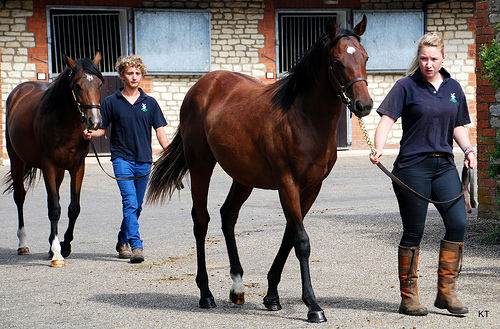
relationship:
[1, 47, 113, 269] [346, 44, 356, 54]
horse with spot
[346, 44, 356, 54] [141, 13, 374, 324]
spot on horse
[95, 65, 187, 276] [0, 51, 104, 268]
boy leading horse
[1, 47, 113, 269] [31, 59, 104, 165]
horse with mane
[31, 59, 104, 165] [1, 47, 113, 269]
mane one horse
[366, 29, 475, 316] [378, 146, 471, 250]
girl wearing pants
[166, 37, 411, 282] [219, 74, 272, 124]
horse has back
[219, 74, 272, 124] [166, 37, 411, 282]
back of horse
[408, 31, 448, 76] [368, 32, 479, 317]
head of girl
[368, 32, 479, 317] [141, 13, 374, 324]
girl leads horse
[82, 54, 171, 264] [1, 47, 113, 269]
boy leads horse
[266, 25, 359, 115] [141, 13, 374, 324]
mane on horse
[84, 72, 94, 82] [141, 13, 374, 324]
spot on horse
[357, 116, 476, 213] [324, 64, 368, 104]
lead hooked to bridle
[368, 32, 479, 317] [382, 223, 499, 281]
girl wearing boots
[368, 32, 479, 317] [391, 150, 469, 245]
girl wearing pants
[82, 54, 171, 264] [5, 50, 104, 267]
boy walking horse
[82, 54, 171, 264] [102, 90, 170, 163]
boy wearing shirt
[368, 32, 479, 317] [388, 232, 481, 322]
girl wearing boots